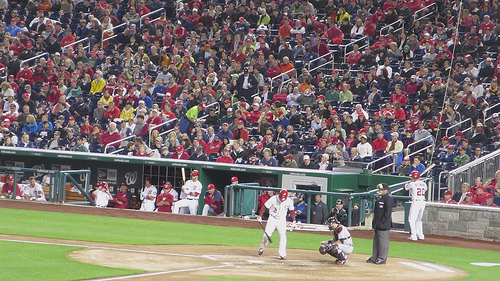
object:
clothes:
[258, 196, 289, 258]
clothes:
[404, 182, 428, 239]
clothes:
[173, 180, 203, 216]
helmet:
[278, 189, 288, 202]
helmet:
[410, 170, 421, 180]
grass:
[0, 246, 64, 281]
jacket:
[371, 195, 395, 231]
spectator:
[103, 101, 119, 119]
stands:
[2, 0, 500, 159]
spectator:
[280, 55, 295, 75]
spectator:
[218, 122, 233, 140]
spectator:
[352, 134, 374, 161]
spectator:
[60, 28, 77, 48]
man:
[317, 217, 356, 266]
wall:
[435, 204, 497, 240]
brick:
[439, 212, 460, 220]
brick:
[448, 221, 466, 230]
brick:
[459, 210, 477, 221]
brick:
[468, 223, 482, 229]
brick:
[485, 231, 499, 238]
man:
[119, 101, 135, 122]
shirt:
[121, 108, 133, 119]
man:
[89, 70, 107, 93]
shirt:
[90, 79, 105, 91]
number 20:
[416, 187, 425, 196]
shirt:
[405, 180, 430, 203]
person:
[171, 144, 191, 159]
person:
[257, 148, 280, 167]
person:
[437, 189, 459, 205]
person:
[338, 84, 354, 101]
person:
[320, 22, 345, 46]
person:
[47, 131, 66, 151]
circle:
[64, 242, 471, 280]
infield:
[0, 209, 500, 281]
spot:
[470, 259, 500, 269]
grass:
[399, 251, 499, 258]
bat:
[258, 221, 275, 244]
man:
[325, 85, 340, 100]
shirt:
[324, 91, 338, 101]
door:
[283, 176, 328, 222]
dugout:
[0, 151, 376, 226]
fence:
[2, 167, 89, 208]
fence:
[220, 185, 375, 226]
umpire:
[365, 183, 399, 265]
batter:
[255, 188, 299, 260]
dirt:
[252, 261, 313, 272]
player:
[404, 167, 433, 243]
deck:
[428, 243, 500, 259]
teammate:
[92, 182, 114, 209]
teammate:
[112, 182, 133, 210]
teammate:
[138, 177, 158, 212]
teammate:
[172, 168, 205, 217]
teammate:
[19, 176, 48, 202]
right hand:
[254, 215, 264, 222]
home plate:
[245, 258, 265, 265]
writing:
[378, 201, 386, 205]